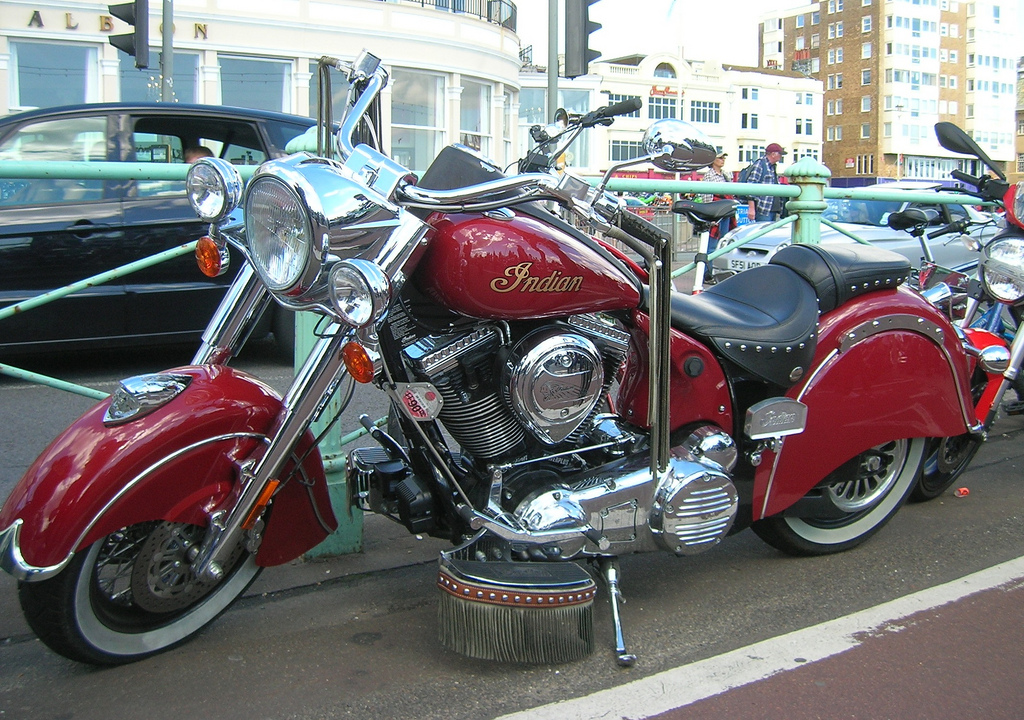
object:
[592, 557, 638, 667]
kick stand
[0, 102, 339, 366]
car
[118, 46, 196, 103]
window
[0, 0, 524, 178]
building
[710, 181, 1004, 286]
vehicles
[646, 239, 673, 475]
tassels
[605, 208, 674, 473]
handlebars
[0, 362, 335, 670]
wheelon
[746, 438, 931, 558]
wheel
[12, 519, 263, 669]
tire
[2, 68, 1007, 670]
bike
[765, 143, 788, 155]
baseball cap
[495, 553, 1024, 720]
line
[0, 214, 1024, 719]
pavement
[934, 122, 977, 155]
mirror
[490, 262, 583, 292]
letters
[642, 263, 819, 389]
seat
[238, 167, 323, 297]
headlight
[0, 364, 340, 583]
fender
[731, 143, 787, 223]
man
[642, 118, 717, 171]
rearview mirror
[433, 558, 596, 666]
foot rest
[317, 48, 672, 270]
handle bars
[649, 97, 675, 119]
window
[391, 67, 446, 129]
window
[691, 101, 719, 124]
window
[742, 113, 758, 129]
window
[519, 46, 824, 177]
building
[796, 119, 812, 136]
window